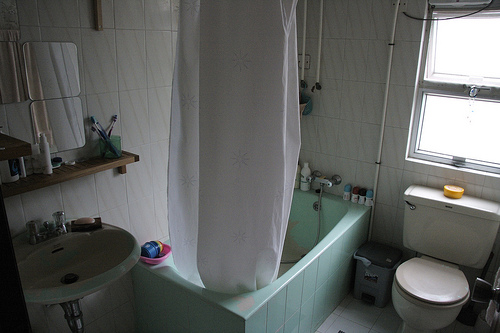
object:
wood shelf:
[0, 148, 142, 201]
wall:
[297, 0, 499, 267]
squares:
[1, 41, 26, 105]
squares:
[25, 41, 80, 101]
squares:
[0, 101, 35, 149]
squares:
[28, 96, 86, 155]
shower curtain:
[167, 0, 302, 294]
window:
[415, 91, 499, 165]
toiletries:
[1, 152, 20, 182]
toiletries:
[16, 153, 26, 176]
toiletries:
[29, 143, 44, 175]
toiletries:
[37, 131, 54, 174]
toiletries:
[50, 156, 65, 167]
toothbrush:
[107, 115, 117, 137]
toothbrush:
[87, 125, 99, 136]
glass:
[98, 134, 123, 158]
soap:
[72, 216, 95, 224]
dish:
[67, 217, 104, 233]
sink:
[9, 217, 142, 304]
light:
[417, 94, 500, 164]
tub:
[137, 185, 382, 331]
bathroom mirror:
[22, 41, 82, 101]